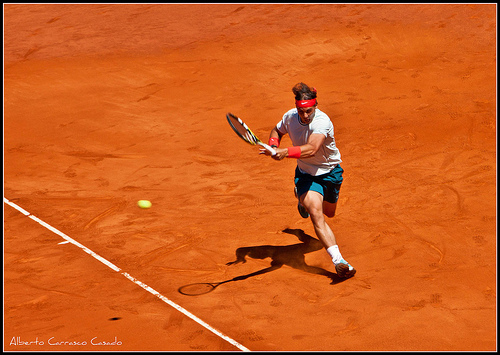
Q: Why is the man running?
A: To be in position to hit the ball.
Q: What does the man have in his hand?
A: Tennis racket.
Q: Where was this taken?
A: A tennis court.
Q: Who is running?
A: Tennis player.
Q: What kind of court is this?
A: Clay.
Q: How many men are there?
A: One.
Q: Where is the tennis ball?
A: In the air heading for the man.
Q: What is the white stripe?
A: Foul line.